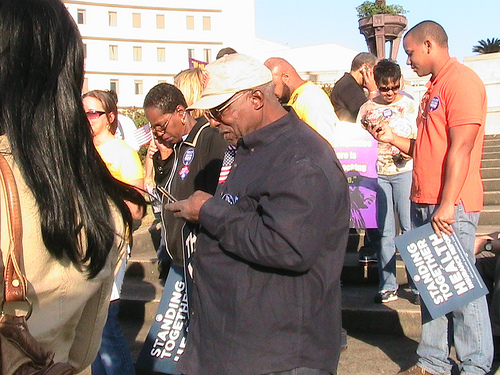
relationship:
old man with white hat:
[153, 54, 350, 373] [186, 54, 276, 110]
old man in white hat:
[153, 54, 350, 373] [186, 54, 276, 110]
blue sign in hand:
[393, 222, 490, 320] [427, 206, 458, 239]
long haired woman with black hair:
[0, 1, 141, 373] [0, 1, 124, 275]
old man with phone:
[153, 54, 350, 373] [156, 184, 185, 221]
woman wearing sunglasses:
[73, 90, 145, 223] [82, 106, 108, 128]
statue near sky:
[355, 0, 406, 68] [254, 2, 495, 58]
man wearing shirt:
[359, 18, 496, 372] [412, 56, 488, 216]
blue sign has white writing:
[393, 222, 490, 320] [408, 237, 469, 302]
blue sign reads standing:
[393, 222, 490, 320] [404, 244, 444, 308]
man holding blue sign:
[359, 18, 496, 372] [393, 222, 490, 320]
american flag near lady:
[133, 122, 157, 151] [143, 82, 223, 269]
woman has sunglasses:
[73, 90, 145, 223] [82, 106, 108, 128]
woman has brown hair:
[73, 90, 145, 223] [84, 91, 122, 135]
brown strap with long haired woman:
[0, 152, 37, 335] [0, 1, 141, 373]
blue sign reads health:
[393, 222, 490, 320] [426, 233, 470, 300]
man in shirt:
[359, 18, 496, 372] [412, 56, 488, 216]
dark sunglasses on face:
[379, 85, 403, 96] [371, 57, 402, 101]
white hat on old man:
[186, 54, 276, 110] [153, 54, 350, 373]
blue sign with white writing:
[393, 222, 490, 320] [408, 237, 469, 302]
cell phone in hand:
[362, 117, 385, 138] [370, 124, 396, 145]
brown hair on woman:
[84, 91, 122, 135] [73, 90, 145, 223]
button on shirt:
[429, 94, 440, 117] [412, 56, 488, 216]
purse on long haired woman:
[0, 315, 76, 373] [0, 1, 141, 373]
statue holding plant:
[355, 0, 406, 68] [354, 2, 405, 17]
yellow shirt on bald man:
[290, 81, 344, 148] [261, 57, 341, 144]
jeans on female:
[379, 167, 413, 300] [359, 62, 418, 306]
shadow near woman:
[118, 255, 156, 352] [73, 90, 145, 223]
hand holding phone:
[172, 189, 213, 229] [156, 184, 185, 221]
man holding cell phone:
[359, 18, 496, 372] [362, 117, 385, 138]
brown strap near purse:
[0, 152, 37, 335] [0, 315, 76, 373]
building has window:
[51, 0, 256, 109] [130, 12, 146, 32]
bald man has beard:
[261, 57, 341, 144] [278, 82, 293, 106]